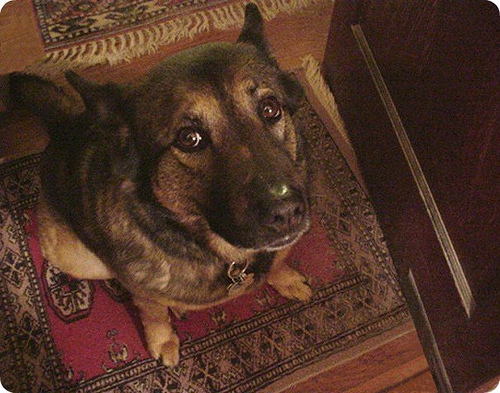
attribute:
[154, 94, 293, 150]
eyes — begging, reflecting, brown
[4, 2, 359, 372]
dog — sitting, looking, black, tan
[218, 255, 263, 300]
tags — silver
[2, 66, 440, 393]
rug — black tan, red, patterned, tan, black,, oriental, brown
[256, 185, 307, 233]
nose — brown, black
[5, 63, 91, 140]
tail — bushy, thick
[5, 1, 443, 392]
floor — hardwood, wooden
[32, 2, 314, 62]
fringe — white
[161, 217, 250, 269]
collar — metal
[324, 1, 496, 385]
door — brown, wooden, open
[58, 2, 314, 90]
ears — pointed